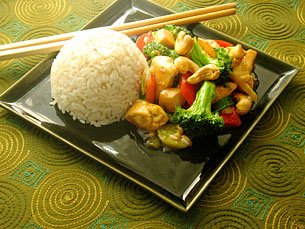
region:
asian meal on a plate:
[20, 6, 267, 199]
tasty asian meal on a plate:
[5, 15, 274, 201]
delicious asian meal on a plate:
[26, 17, 286, 209]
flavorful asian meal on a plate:
[20, 19, 289, 213]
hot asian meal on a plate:
[12, 13, 272, 210]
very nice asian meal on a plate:
[20, 16, 286, 208]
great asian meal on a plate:
[6, 15, 286, 214]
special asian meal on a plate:
[13, 17, 285, 216]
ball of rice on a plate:
[45, 29, 144, 139]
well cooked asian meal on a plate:
[16, 13, 280, 209]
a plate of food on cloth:
[0, 2, 301, 224]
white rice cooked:
[86, 35, 109, 75]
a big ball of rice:
[38, 27, 153, 131]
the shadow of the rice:
[33, 115, 131, 163]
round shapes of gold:
[19, 156, 117, 226]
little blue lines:
[5, 160, 49, 189]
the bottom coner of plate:
[142, 170, 210, 218]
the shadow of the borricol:
[182, 131, 226, 186]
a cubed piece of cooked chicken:
[118, 99, 170, 129]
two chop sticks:
[1, 0, 233, 59]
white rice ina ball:
[37, 25, 146, 119]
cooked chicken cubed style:
[125, 93, 168, 135]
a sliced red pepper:
[137, 71, 160, 103]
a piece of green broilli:
[172, 79, 223, 134]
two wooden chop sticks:
[0, 0, 238, 55]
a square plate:
[0, 4, 304, 218]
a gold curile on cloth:
[241, 0, 301, 41]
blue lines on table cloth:
[8, 155, 49, 190]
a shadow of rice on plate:
[46, 117, 138, 159]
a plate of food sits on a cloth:
[0, 1, 304, 203]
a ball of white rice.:
[39, 20, 162, 129]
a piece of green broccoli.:
[176, 87, 232, 133]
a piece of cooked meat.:
[117, 95, 174, 142]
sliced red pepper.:
[219, 107, 247, 130]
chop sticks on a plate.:
[0, 0, 240, 61]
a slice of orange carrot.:
[143, 70, 166, 106]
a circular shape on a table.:
[27, 168, 105, 227]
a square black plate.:
[0, 2, 299, 202]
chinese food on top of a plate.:
[46, 12, 273, 164]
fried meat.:
[125, 96, 180, 137]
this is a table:
[15, 151, 70, 226]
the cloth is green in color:
[39, 193, 100, 222]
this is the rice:
[82, 33, 124, 110]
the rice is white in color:
[74, 48, 98, 87]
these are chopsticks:
[133, 3, 235, 20]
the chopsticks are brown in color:
[191, 9, 216, 18]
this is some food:
[151, 35, 244, 122]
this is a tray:
[147, 155, 191, 185]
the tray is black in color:
[161, 160, 196, 187]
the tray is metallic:
[155, 165, 191, 191]